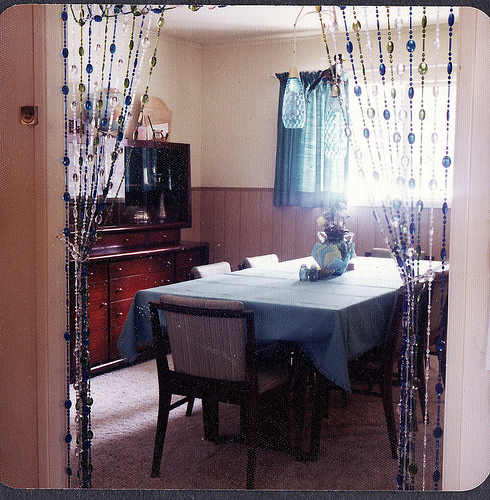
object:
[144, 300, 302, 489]
chair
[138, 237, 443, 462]
table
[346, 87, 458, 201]
window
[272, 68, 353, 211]
curtains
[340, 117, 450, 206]
beads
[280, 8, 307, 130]
light fixture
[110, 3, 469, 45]
ceiling